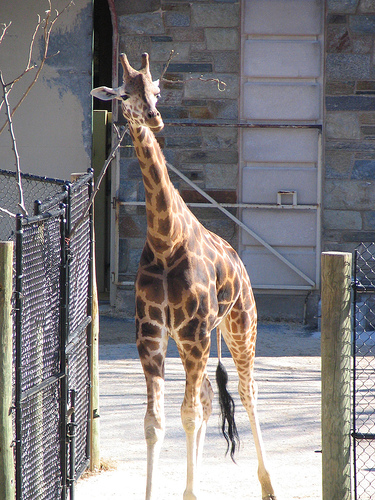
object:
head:
[87, 45, 181, 136]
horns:
[116, 48, 135, 71]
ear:
[89, 81, 125, 107]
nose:
[145, 109, 165, 121]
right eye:
[119, 93, 132, 103]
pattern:
[140, 254, 198, 307]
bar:
[66, 385, 80, 498]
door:
[13, 202, 72, 499]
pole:
[84, 0, 126, 300]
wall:
[331, 9, 374, 218]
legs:
[174, 321, 211, 499]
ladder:
[236, 5, 328, 295]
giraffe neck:
[125, 131, 183, 232]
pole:
[321, 245, 354, 500]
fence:
[353, 245, 374, 499]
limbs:
[0, 3, 82, 205]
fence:
[2, 180, 92, 469]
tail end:
[215, 360, 242, 467]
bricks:
[194, 27, 241, 56]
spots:
[154, 184, 172, 215]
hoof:
[258, 490, 278, 499]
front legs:
[133, 316, 168, 498]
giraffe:
[88, 46, 279, 500]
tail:
[211, 325, 245, 462]